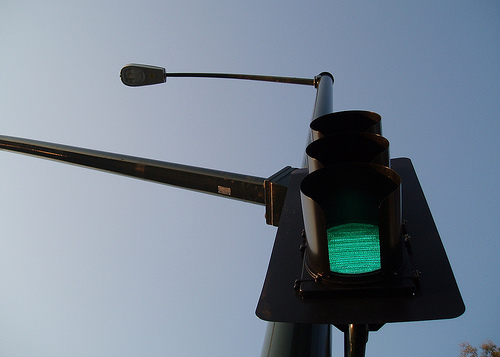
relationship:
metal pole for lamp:
[303, 70, 333, 175] [118, 61, 165, 87]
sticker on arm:
[213, 182, 233, 195] [0, 133, 267, 204]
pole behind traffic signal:
[258, 63, 352, 354] [261, 101, 465, 333]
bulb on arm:
[120, 65, 161, 85] [167, 69, 312, 85]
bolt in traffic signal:
[284, 274, 314, 303] [246, 102, 474, 334]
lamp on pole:
[118, 61, 165, 87] [165, 52, 344, 354]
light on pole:
[268, 120, 472, 355] [263, 54, 343, 354]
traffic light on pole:
[300, 105, 416, 312] [348, 319, 366, 355]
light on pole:
[256, 107, 467, 355] [258, 63, 352, 354]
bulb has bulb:
[325, 217, 382, 276] [325, 217, 382, 276]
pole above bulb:
[247, 71, 336, 357] [325, 217, 382, 276]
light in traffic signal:
[256, 107, 467, 355] [246, 102, 474, 334]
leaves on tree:
[455, 337, 498, 354] [452, 332, 497, 354]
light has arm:
[256, 107, 467, 355] [166, 66, 323, 94]